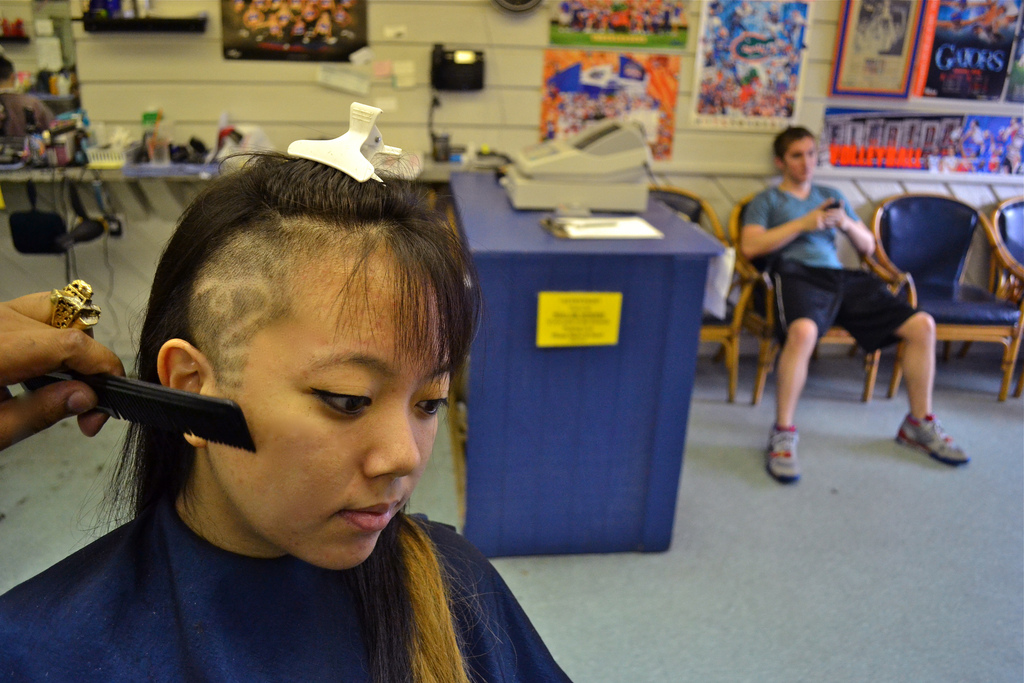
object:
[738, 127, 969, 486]
boy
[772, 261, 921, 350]
shorts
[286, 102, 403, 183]
hair clip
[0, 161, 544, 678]
person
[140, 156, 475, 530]
hair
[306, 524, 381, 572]
chin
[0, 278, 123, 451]
person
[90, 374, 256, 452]
comb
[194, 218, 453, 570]
head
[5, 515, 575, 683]
cloth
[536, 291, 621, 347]
sign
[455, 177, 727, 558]
counter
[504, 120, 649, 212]
cash register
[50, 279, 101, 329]
ring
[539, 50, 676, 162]
poster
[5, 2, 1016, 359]
wall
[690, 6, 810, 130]
poster